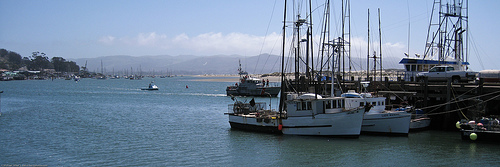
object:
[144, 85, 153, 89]
person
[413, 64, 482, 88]
truck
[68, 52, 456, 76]
mountains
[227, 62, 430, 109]
dock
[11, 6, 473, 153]
photo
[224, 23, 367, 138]
boat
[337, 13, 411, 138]
boat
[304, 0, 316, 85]
masts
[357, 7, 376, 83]
masts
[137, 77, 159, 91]
boat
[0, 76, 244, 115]
sea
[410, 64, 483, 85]
vehicle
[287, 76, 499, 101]
pier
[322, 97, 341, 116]
windows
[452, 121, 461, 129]
floats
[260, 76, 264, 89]
people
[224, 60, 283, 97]
boat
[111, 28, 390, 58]
clouds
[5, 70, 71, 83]
buildings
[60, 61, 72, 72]
trees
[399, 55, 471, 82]
building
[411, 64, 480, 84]
car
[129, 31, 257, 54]
clouds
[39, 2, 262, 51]
sky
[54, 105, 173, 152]
water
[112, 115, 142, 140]
ripples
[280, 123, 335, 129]
stripe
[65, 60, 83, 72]
trees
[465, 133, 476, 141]
things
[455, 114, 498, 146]
boat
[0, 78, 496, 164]
water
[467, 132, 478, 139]
ball